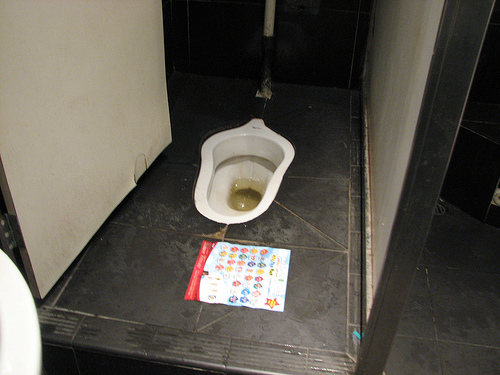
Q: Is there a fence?
A: No, there are no fences.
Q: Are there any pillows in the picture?
A: No, there are no pillows.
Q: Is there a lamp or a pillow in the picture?
A: No, there are no pillows or lamps.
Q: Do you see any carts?
A: No, there are no carts.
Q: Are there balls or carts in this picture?
A: No, there are no carts or balls.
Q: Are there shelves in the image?
A: No, there are no shelves.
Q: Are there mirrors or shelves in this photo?
A: No, there are no shelves or mirrors.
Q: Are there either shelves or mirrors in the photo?
A: No, there are no shelves or mirrors.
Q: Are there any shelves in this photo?
A: No, there are no shelves.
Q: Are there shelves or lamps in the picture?
A: No, there are no shelves or lamps.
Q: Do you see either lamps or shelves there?
A: No, there are no shelves or lamps.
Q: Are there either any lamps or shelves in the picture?
A: No, there are no shelves or lamps.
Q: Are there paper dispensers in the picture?
A: No, there are no paper dispensers.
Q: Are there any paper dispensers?
A: No, there are no paper dispensers.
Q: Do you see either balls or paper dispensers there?
A: No, there are no paper dispensers or balls.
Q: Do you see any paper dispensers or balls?
A: No, there are no paper dispensers or balls.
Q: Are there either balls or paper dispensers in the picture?
A: No, there are no paper dispensers or balls.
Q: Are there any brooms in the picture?
A: No, there are no brooms.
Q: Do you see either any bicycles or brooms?
A: No, there are no brooms or bicycles.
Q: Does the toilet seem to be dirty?
A: Yes, the toilet is dirty.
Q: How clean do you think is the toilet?
A: The toilet is dirty.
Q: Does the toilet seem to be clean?
A: No, the toilet is dirty.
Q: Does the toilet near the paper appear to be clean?
A: No, the toilet is dirty.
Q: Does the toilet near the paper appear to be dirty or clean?
A: The toilet is dirty.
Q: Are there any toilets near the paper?
A: Yes, there is a toilet near the paper.